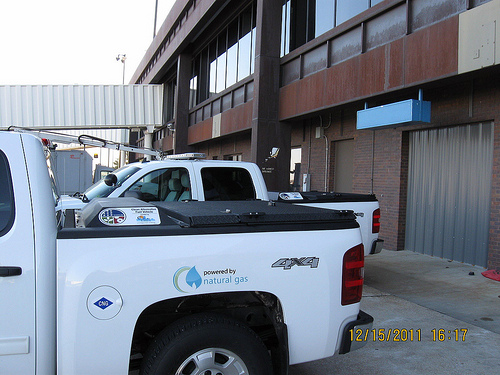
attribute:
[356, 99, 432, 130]
box — blue, attached, hanging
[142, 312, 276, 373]
tire — black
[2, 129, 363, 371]
truck — white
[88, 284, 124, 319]
cover — white, round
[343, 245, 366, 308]
light — red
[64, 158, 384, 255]
truck — white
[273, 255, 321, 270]
numbers — gray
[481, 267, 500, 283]
rag — red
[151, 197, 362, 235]
cover — black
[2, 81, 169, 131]
walkway — attached, white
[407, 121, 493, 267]
door — metal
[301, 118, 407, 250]
wall — brick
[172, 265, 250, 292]
cirlce — large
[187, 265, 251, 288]
logo — blue